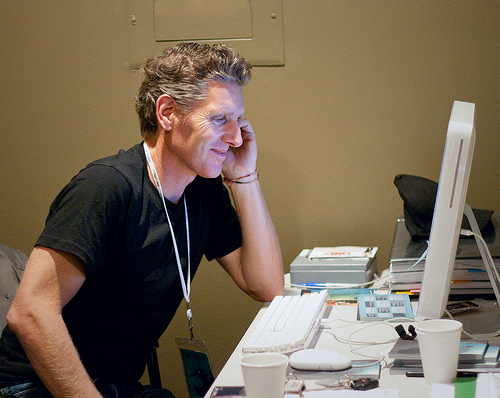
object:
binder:
[386, 212, 500, 301]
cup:
[239, 351, 290, 397]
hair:
[135, 40, 254, 139]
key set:
[317, 363, 332, 370]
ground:
[426, 103, 446, 120]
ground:
[406, 135, 414, 172]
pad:
[287, 364, 381, 382]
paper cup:
[415, 318, 463, 383]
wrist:
[224, 168, 259, 186]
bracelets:
[221, 169, 260, 185]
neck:
[144, 125, 197, 203]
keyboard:
[241, 289, 330, 357]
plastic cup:
[238, 352, 290, 397]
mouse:
[289, 348, 353, 371]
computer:
[414, 99, 500, 338]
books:
[289, 246, 379, 286]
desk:
[198, 303, 500, 398]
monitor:
[416, 97, 477, 320]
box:
[287, 244, 379, 286]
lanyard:
[140, 138, 196, 344]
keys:
[315, 375, 383, 390]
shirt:
[0, 140, 244, 379]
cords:
[313, 305, 484, 368]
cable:
[442, 308, 477, 339]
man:
[0, 40, 285, 396]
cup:
[415, 318, 464, 385]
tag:
[136, 140, 215, 398]